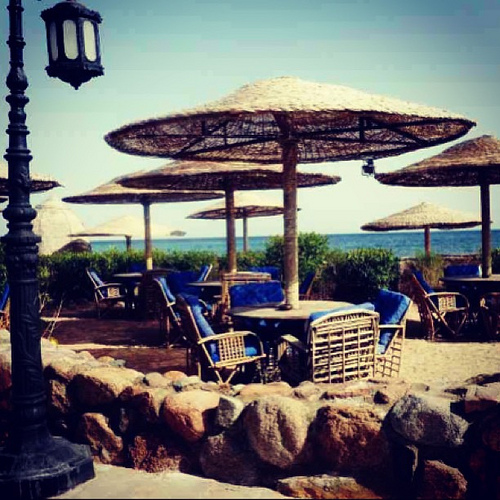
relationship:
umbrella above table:
[113, 73, 469, 183] [230, 300, 352, 319]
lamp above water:
[39, 2, 104, 90] [67, 228, 500, 266]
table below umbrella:
[230, 300, 352, 319] [113, 73, 469, 183]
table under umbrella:
[230, 300, 352, 319] [113, 73, 469, 183]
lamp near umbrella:
[39, 2, 104, 90] [113, 73, 469, 183]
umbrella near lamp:
[113, 73, 469, 183] [39, 2, 104, 90]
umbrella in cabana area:
[102, 75, 476, 312] [0, 254, 499, 498]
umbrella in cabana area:
[373, 133, 498, 193] [0, 254, 499, 498]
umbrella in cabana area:
[119, 160, 341, 279] [0, 254, 499, 498]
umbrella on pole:
[102, 75, 476, 312] [273, 131, 307, 307]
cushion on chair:
[183, 294, 256, 362] [176, 293, 272, 389]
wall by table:
[70, 374, 500, 499] [234, 295, 359, 371]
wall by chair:
[70, 374, 500, 499] [174, 296, 275, 381]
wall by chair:
[70, 374, 500, 499] [271, 302, 381, 383]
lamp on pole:
[36, 2, 110, 93] [1, 4, 96, 492]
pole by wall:
[1, 4, 96, 492] [55, 350, 495, 491]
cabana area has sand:
[56, 264, 496, 390] [404, 339, 489, 381]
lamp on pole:
[39, 2, 104, 90] [1, 4, 96, 492]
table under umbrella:
[225, 295, 374, 324] [102, 75, 476, 312]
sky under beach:
[108, 4, 498, 56] [39, 237, 498, 399]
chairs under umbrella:
[173, 294, 278, 384] [102, 75, 476, 312]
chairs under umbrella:
[271, 302, 380, 386] [102, 75, 476, 312]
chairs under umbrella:
[369, 285, 406, 378] [102, 75, 476, 312]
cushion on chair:
[183, 293, 256, 359] [175, 293, 268, 382]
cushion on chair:
[308, 300, 376, 320] [281, 300, 382, 383]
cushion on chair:
[372, 286, 410, 345] [369, 285, 415, 379]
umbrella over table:
[113, 73, 469, 183] [235, 297, 355, 319]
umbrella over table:
[373, 133, 499, 278] [440, 272, 498, 307]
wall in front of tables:
[2, 327, 499, 498] [111, 270, 499, 380]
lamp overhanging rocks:
[39, 2, 104, 90] [0, 329, 499, 499]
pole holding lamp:
[0, 4, 95, 500] [39, 2, 104, 90]